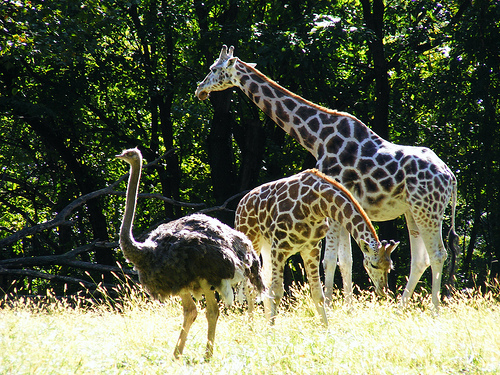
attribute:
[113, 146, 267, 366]
ostrich — standing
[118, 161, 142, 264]
neck — long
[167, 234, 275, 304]
feathers — black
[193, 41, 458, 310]
giraffe — pictured, bending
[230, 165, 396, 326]
giraffe — eating